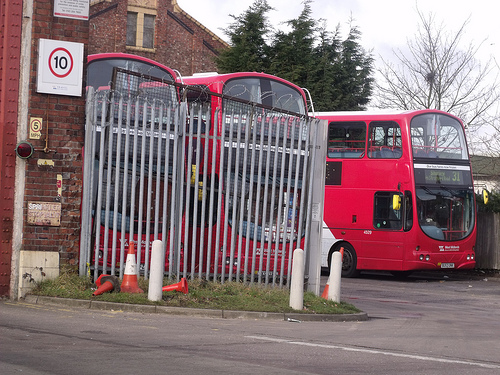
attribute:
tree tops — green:
[219, 1, 371, 111]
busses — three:
[86, 53, 477, 279]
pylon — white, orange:
[120, 243, 145, 293]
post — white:
[329, 250, 341, 302]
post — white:
[146, 237, 166, 301]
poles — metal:
[83, 87, 329, 292]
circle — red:
[47, 47, 74, 76]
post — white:
[330, 252, 340, 301]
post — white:
[288, 249, 305, 310]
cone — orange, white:
[118, 240, 141, 293]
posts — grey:
[79, 85, 102, 288]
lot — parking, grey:
[7, 270, 497, 372]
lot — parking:
[5, 260, 496, 369]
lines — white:
[246, 325, 498, 372]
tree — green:
[211, 1, 380, 116]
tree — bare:
[356, 19, 498, 153]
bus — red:
[302, 96, 484, 280]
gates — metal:
[72, 80, 328, 308]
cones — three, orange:
[87, 241, 192, 315]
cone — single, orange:
[322, 235, 356, 303]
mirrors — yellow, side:
[378, 177, 498, 222]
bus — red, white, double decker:
[315, 111, 481, 276]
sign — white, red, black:
[33, 32, 87, 108]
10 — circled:
[52, 55, 73, 75]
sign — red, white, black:
[23, 112, 53, 151]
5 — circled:
[30, 118, 42, 136]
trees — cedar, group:
[213, 3, 379, 118]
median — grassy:
[34, 242, 367, 329]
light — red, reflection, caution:
[12, 134, 38, 167]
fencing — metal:
[71, 68, 331, 299]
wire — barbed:
[89, 64, 323, 127]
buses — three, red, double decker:
[84, 51, 484, 301]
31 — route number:
[448, 166, 467, 186]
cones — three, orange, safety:
[78, 236, 194, 304]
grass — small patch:
[28, 269, 353, 331]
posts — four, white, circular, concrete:
[144, 235, 352, 314]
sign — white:
[31, 35, 87, 101]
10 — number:
[55, 54, 70, 74]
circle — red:
[44, 44, 79, 82]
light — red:
[12, 137, 37, 164]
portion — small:
[472, 193, 499, 275]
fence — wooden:
[469, 190, 499, 278]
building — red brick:
[87, 1, 243, 70]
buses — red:
[81, 52, 480, 277]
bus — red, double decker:
[291, 108, 477, 275]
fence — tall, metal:
[74, 80, 323, 308]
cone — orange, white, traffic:
[114, 239, 142, 296]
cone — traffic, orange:
[89, 270, 123, 293]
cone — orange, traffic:
[161, 271, 188, 294]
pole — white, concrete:
[284, 247, 304, 309]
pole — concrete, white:
[325, 250, 345, 302]